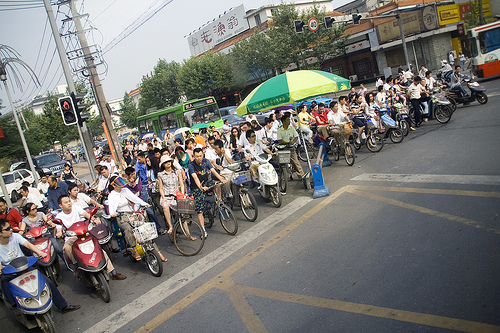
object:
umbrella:
[235, 69, 352, 118]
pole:
[64, 1, 128, 172]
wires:
[0, 43, 24, 57]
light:
[58, 96, 78, 124]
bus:
[134, 95, 224, 141]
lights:
[206, 99, 214, 104]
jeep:
[23, 152, 76, 181]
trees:
[177, 47, 252, 111]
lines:
[220, 274, 272, 332]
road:
[0, 58, 500, 333]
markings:
[347, 171, 499, 183]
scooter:
[0, 253, 62, 332]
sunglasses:
[1, 224, 13, 232]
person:
[1, 217, 81, 326]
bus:
[463, 16, 500, 84]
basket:
[130, 221, 158, 244]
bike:
[116, 204, 164, 276]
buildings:
[180, 0, 340, 124]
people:
[185, 147, 227, 240]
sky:
[0, 0, 361, 116]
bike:
[52, 206, 115, 304]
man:
[53, 193, 130, 281]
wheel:
[28, 312, 55, 333]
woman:
[106, 172, 169, 263]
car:
[0, 167, 43, 205]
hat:
[109, 174, 129, 189]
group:
[0, 51, 475, 319]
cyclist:
[157, 191, 209, 257]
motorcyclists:
[50, 207, 116, 305]